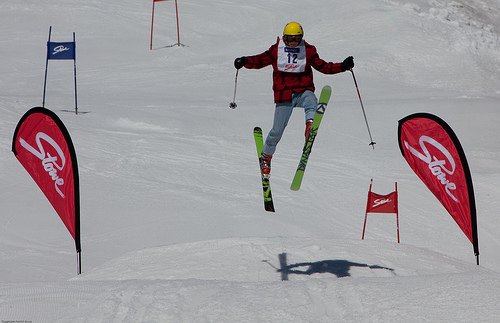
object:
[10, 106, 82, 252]
flags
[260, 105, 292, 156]
leg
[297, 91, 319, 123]
leg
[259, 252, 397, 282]
shadow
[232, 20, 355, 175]
person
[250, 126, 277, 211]
ski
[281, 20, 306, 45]
helmet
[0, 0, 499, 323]
ground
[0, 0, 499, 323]
snow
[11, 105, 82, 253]
banner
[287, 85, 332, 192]
ski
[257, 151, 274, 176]
boot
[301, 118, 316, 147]
boot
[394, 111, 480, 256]
flag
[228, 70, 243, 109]
pole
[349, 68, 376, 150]
pole